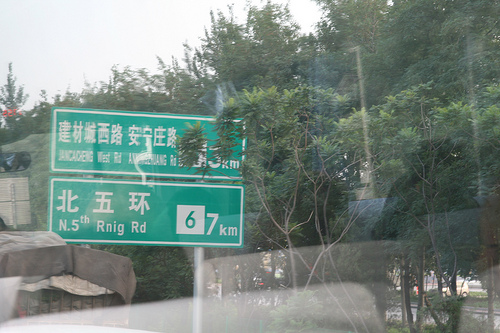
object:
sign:
[51, 105, 254, 184]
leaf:
[270, 169, 276, 178]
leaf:
[311, 132, 318, 142]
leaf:
[323, 131, 328, 141]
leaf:
[299, 153, 309, 159]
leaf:
[259, 122, 268, 131]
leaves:
[416, 64, 454, 93]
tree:
[378, 78, 491, 333]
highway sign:
[47, 105, 251, 248]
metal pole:
[192, 246, 207, 331]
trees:
[171, 79, 385, 333]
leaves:
[440, 104, 475, 121]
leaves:
[294, 88, 322, 106]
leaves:
[376, 5, 420, 41]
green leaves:
[377, 34, 399, 50]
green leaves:
[411, 20, 432, 39]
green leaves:
[319, 65, 341, 79]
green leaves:
[365, 78, 381, 90]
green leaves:
[339, 92, 354, 104]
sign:
[46, 177, 246, 252]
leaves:
[219, 39, 240, 55]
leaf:
[446, 100, 457, 113]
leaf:
[381, 90, 396, 102]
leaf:
[422, 78, 433, 91]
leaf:
[378, 106, 388, 117]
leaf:
[431, 112, 441, 120]